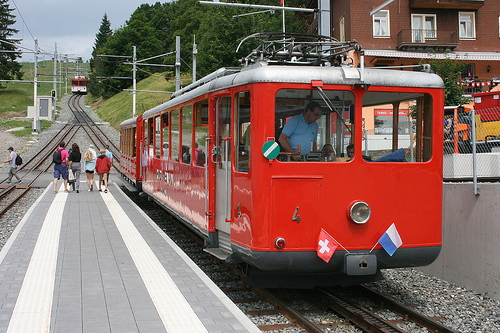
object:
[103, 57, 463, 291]
train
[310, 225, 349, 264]
flag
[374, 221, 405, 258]
flag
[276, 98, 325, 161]
man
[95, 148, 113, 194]
person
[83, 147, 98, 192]
person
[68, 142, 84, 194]
person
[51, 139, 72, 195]
person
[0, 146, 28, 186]
man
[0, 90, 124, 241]
train tracks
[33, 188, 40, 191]
rock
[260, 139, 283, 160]
sign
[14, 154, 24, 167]
backpack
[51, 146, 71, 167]
shirt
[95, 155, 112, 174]
jacket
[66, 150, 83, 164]
shirt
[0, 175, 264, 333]
pavement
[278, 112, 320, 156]
shirt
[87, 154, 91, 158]
hair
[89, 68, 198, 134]
grass